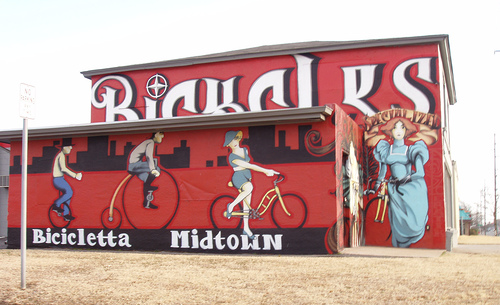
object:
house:
[0, 34, 458, 260]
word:
[388, 57, 436, 117]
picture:
[354, 103, 441, 248]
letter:
[338, 63, 386, 119]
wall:
[85, 40, 446, 248]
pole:
[18, 116, 31, 290]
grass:
[0, 234, 500, 305]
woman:
[368, 116, 430, 248]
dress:
[371, 139, 430, 248]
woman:
[222, 130, 280, 239]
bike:
[209, 174, 309, 229]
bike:
[100, 166, 179, 231]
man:
[50, 139, 81, 221]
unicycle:
[47, 189, 74, 228]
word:
[169, 230, 191, 248]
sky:
[0, 1, 500, 225]